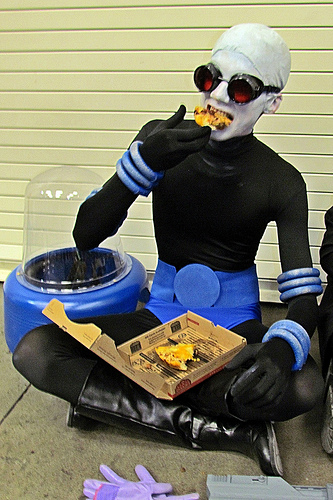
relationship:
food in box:
[153, 337, 204, 375] [50, 267, 264, 393]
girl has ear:
[12, 22, 322, 478] [267, 92, 281, 113]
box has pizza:
[124, 306, 246, 399] [158, 338, 200, 373]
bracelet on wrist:
[108, 134, 178, 199] [131, 143, 142, 166]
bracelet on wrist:
[108, 134, 178, 199] [263, 318, 310, 371]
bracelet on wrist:
[108, 134, 178, 199] [277, 268, 321, 298]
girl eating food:
[12, 22, 322, 478] [192, 103, 226, 128]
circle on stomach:
[169, 260, 228, 319] [165, 193, 271, 309]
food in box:
[130, 310, 220, 412] [38, 293, 251, 404]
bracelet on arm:
[113, 138, 160, 198] [71, 102, 203, 255]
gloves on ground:
[66, 463, 187, 498] [1, 282, 330, 496]